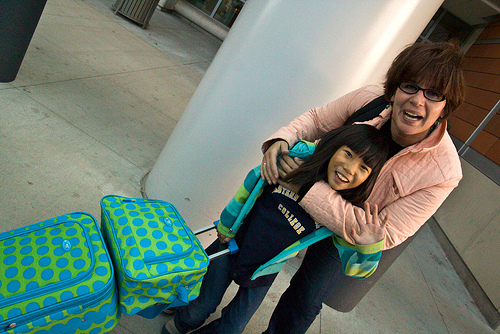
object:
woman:
[163, 42, 469, 334]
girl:
[162, 121, 395, 334]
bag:
[100, 191, 217, 320]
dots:
[146, 228, 164, 239]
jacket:
[257, 81, 465, 254]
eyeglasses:
[397, 79, 450, 102]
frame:
[397, 83, 444, 103]